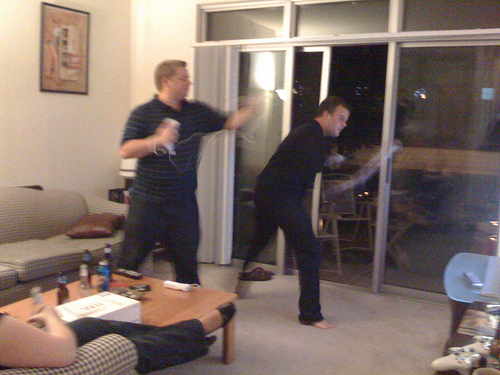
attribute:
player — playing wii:
[231, 82, 400, 333]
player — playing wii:
[93, 55, 270, 307]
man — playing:
[95, 33, 273, 291]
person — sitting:
[3, 284, 258, 368]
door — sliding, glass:
[239, 42, 391, 295]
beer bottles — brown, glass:
[53, 242, 115, 305]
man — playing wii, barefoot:
[240, 95, 353, 333]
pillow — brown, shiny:
[64, 210, 121, 237]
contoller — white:
[432, 334, 492, 374]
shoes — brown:
[232, 265, 275, 279]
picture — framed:
[25, 0, 114, 106]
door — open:
[290, 44, 376, 289]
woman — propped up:
[2, 297, 236, 373]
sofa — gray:
[0, 179, 141, 299]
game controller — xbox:
[433, 338, 494, 373]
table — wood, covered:
[3, 271, 235, 348]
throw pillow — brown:
[63, 209, 127, 237]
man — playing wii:
[108, 53, 277, 283]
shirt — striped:
[116, 90, 226, 191]